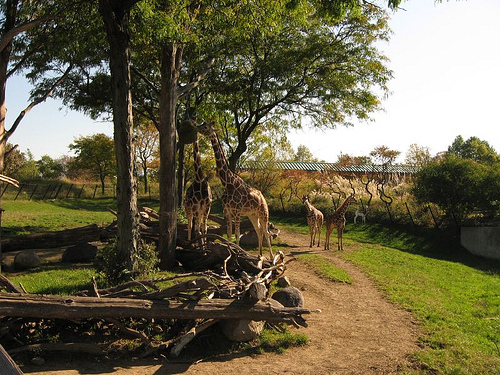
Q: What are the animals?
A: Giraffes.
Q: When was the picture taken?
A: Daytime.